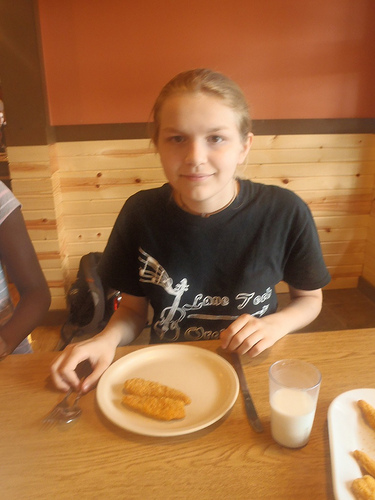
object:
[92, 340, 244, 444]
plate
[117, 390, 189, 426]
chicken tender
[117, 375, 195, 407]
chicken tender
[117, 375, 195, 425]
chicken tenders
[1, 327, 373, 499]
table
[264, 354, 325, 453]
glass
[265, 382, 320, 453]
milk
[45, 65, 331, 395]
girl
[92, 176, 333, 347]
shirt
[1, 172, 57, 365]
person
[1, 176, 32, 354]
shirt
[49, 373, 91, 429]
spoon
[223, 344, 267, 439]
knife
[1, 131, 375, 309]
wall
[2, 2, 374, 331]
back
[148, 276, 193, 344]
violin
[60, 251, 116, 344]
backpack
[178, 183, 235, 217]
necklace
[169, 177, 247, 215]
neck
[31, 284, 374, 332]
floor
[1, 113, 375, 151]
chair-rail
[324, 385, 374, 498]
platter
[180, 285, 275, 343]
wording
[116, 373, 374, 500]
food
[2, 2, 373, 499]
shot